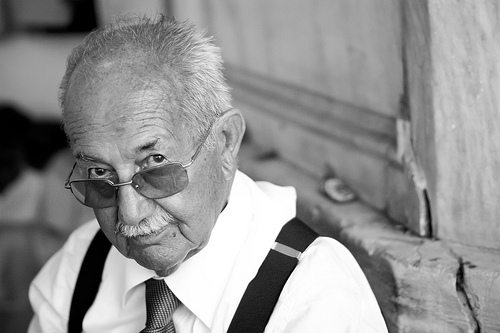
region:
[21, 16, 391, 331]
The man is old.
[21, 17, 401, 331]
The man has hair.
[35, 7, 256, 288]
Man's hair is short.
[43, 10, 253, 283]
Man is wearing glasses.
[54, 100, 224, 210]
Man's glasses are tinted.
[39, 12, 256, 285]
The man has eyes.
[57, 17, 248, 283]
Man's eyes are open.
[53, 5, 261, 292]
Man has a moustache.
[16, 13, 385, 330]
Man is wearing suspenders.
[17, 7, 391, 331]
Man is wearing shirt.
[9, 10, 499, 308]
black and white photo of an elderly man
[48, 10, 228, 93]
short gray hair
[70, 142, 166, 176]
eyes of an elderly man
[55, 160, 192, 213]
tinted glasses on a man's nose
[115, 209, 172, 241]
elderly man's white mustache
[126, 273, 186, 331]
knot of a necktie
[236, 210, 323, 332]
left suspender strap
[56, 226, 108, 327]
right suspender strap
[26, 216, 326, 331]
white Oxford shirt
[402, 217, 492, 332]
cracked cement wall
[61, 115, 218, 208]
glasses on a man's face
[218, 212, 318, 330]
a black suspender strap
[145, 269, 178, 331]
a striped tie on a man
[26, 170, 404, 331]
a white shirt on a man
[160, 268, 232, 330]
the collar of a white shirt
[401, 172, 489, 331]
a crack in a wall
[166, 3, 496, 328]
a concrete wall behind a man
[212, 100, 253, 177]
the ear of a man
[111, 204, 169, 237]
a moustache on a man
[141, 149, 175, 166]
an eye on a man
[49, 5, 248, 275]
the head of a man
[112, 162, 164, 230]
the nose of a man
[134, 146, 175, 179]
the eye of a man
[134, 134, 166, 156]
the eyebrow of a man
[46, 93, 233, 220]
a pair of glasses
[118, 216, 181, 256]
the mouth of a man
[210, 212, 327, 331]
a black suspender on the man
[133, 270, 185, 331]
a black and gray tie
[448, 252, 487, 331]
a crack in the wall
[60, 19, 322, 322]
man peering over glasses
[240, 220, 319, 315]
suspender on man's shoulder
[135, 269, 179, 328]
tie on man's neck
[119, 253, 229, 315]
white collar of shirt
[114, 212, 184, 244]
mustache on man's face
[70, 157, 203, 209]
glasses on man's face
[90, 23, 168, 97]
top of balding head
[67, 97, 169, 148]
creases in man's forehead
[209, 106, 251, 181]
ear with long lobe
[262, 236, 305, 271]
metal on black suspender